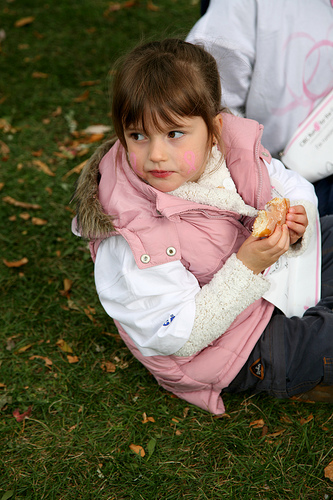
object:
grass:
[2, 2, 332, 499]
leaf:
[4, 254, 29, 271]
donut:
[251, 197, 290, 239]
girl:
[65, 36, 333, 416]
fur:
[71, 134, 115, 235]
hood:
[69, 136, 161, 239]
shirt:
[184, 1, 332, 156]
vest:
[70, 112, 278, 421]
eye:
[167, 130, 188, 139]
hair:
[108, 35, 224, 153]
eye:
[128, 130, 149, 142]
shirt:
[93, 143, 320, 358]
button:
[166, 246, 177, 257]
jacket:
[68, 109, 277, 417]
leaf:
[128, 443, 147, 459]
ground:
[1, 1, 333, 500]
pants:
[221, 214, 332, 399]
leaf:
[2, 194, 42, 213]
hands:
[236, 224, 291, 274]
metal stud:
[166, 245, 177, 258]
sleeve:
[93, 236, 199, 359]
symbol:
[276, 23, 332, 129]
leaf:
[99, 359, 117, 375]